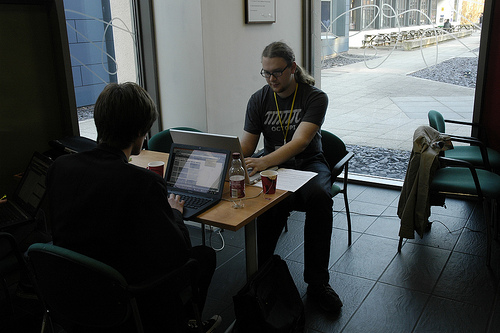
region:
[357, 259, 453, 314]
this is the floor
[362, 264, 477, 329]
the floor is made of tiles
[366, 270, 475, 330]
the tiles are big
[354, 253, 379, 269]
the tiles are black in color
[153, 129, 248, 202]
these are two laptops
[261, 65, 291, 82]
this is a pair of spectacles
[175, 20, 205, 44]
this is the wall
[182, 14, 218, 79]
the wall is white in color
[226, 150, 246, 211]
this is a bottle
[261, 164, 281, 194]
this is a cup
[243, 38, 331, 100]
MAN WITH LONG HAIR IN PONY TAIL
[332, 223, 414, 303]
GREY CERAMIC TILE FLOORING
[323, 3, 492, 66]
WHITE GRAPHICS ON LARGE WINDOW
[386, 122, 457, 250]
TAN JACKET HANGING ON BACK OF CHAIR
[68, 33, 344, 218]
TWO MEN SITTING AT TABLE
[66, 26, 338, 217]
TWO MEN USING LAPTOP COMPUTERS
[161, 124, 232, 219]
BLACK LAPTOM THAT PERSON IS TYPING ON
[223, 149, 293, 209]
DRINK BOTTLE AND BROWN CUP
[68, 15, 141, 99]
VIEW OF BUILDING NEXT DOOR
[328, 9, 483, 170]
VIEW OF SIDEWALK FROM INSIDE BUILDING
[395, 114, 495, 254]
Jacket on a chair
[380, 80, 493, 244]
Two green chairs in room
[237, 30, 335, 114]
Man who is wearing glasses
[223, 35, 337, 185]
Man wearing a lanyard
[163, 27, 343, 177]
Man using his laptop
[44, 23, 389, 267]
Two men using their laptops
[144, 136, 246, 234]
Black laptop on desk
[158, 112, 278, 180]
Silver laptop on desk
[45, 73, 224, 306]
Man wearing a black suit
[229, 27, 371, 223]
Man wearing a black shirt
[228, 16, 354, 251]
man with long hair at table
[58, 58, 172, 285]
man with long hair at table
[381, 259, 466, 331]
black tiles on floor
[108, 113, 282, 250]
wooden table with laptops atop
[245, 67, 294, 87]
eye glasses on man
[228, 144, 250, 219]
plastic bottle on table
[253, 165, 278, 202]
paper cup on table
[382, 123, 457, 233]
sweater on green chair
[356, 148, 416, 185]
gray stones outside window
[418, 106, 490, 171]
green cushions on chairs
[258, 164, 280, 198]
cup on a table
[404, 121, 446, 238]
jacket hanging on a chair back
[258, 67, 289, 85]
eye glasses on a person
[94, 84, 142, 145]
short hair on a person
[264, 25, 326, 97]
long hair on a person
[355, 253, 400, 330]
square tiles on the floor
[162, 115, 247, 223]
two laptops on a table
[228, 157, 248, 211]
empty plastic beverage bottle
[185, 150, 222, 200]
reflection on a lap top screen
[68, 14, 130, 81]
lines on the window